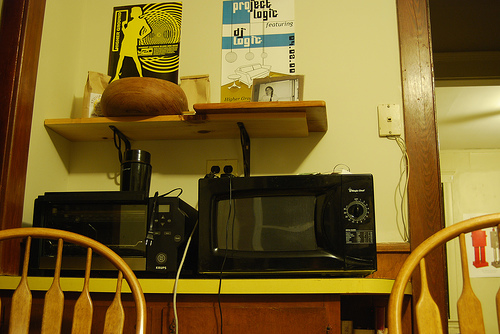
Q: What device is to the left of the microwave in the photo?
A: Toaster Oven.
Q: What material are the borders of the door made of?
A: Wood.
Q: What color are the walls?
A: Egg shell white.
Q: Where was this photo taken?
A: The kitchen.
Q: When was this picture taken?
A: Night time.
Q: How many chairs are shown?
A: Two.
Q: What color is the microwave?
A: Black.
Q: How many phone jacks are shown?
A: One.